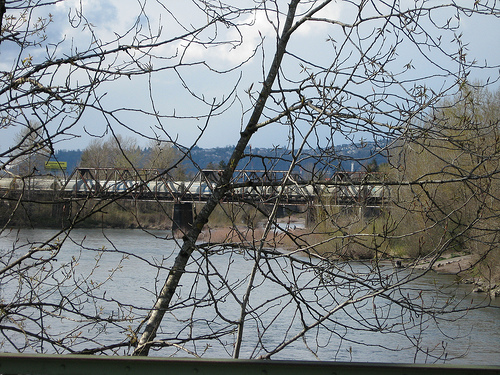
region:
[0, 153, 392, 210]
train on a bridge over a river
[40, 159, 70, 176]
yellow billboard behind the train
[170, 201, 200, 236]
bridge support in the river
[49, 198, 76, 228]
bridge support in the river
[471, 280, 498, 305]
rockers at the edge of the river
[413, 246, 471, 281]
sandy looking beach area by the river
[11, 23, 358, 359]
barren tree branches with the train behind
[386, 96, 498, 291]
overgrown brush area on the river bank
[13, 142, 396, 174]
hill in the background with trees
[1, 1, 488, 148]
cloudy sky with some light on clouds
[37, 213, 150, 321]
The water is very calm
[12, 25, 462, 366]
The tree has no leaves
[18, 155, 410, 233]
The bridge over the water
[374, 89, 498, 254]
The tree has brown leaves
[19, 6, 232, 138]
The sky is clear and blue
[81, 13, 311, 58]
The clouds are fluffy and white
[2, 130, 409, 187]
The mountains are very vast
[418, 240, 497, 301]
The dirt on the side of the water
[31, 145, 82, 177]
The sign in the distance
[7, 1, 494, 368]
river scene with a bridge and trees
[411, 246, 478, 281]
sandy beach area on a river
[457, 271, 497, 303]
rocks on the side of a river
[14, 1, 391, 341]
barren tree branches with river in background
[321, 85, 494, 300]
overgrown brush on the river bank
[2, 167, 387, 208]
train on a bridge crossing a river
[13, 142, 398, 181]
trees hills in the background behind the train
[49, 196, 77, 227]
support for the bridge in the river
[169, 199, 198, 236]
support for the bridge in the river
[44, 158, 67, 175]
yellow billboard sign behind the train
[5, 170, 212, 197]
a bridge a cross a river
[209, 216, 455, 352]
dry branches of a tree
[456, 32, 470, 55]
dry leaves on a branch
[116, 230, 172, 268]
a river full of water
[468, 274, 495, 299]
stones on the river bank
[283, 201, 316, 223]
under the bridge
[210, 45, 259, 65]
white clouds in the sky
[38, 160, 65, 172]
a sign post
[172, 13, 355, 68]
clouds in the sky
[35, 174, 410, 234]
a bridge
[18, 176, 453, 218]
a bridge over the water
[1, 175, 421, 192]
a train on the bridge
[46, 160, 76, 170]
a yellow billboard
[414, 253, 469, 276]
dirt next to the water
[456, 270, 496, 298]
rocks next to the water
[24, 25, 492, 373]
trees in front of the water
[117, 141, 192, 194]
a branch on the tree